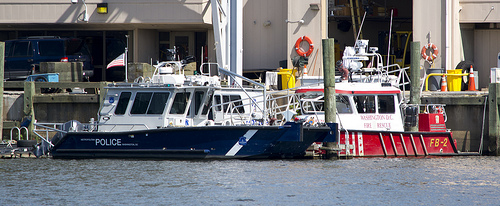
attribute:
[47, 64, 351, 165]
boat — blue, white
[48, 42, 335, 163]
blue boat — police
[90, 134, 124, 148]
writing — white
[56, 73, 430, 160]
boat — yellow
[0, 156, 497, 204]
ocean — slow , flowing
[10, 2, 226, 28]
wall — stone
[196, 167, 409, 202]
section — slow flowing